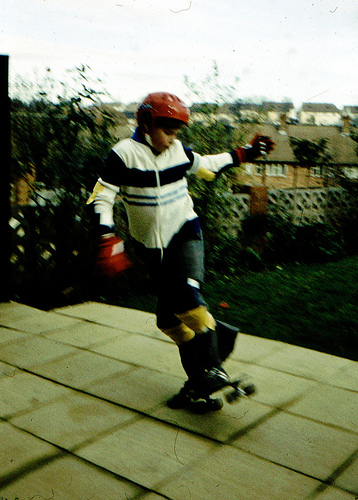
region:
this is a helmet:
[147, 71, 218, 172]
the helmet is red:
[113, 121, 179, 169]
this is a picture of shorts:
[126, 243, 221, 320]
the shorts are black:
[145, 236, 226, 319]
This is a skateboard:
[187, 376, 260, 399]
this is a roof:
[270, 141, 295, 163]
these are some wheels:
[142, 360, 267, 421]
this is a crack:
[156, 339, 177, 488]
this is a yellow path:
[167, 300, 215, 336]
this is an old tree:
[56, 177, 82, 267]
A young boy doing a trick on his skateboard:
[75, 88, 275, 416]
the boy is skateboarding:
[88, 84, 287, 418]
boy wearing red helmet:
[130, 87, 196, 140]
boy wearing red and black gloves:
[70, 96, 286, 412]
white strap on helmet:
[146, 125, 159, 150]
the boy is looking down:
[77, 92, 279, 417]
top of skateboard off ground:
[203, 372, 258, 408]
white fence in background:
[5, 184, 352, 288]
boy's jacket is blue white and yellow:
[89, 132, 234, 253]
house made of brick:
[241, 159, 357, 188]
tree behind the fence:
[8, 77, 131, 201]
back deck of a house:
[3, 301, 355, 498]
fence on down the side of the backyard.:
[9, 189, 353, 268]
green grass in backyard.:
[125, 254, 354, 358]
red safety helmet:
[134, 94, 190, 121]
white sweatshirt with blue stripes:
[88, 133, 240, 250]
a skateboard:
[168, 378, 254, 419]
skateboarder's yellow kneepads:
[159, 309, 212, 342]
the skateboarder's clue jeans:
[155, 243, 239, 372]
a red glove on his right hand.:
[96, 238, 130, 272]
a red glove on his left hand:
[235, 136, 275, 164]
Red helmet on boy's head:
[136, 92, 189, 126]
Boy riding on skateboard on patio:
[85, 91, 277, 414]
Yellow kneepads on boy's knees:
[157, 304, 217, 344]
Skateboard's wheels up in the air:
[167, 374, 257, 413]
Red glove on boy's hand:
[95, 236, 132, 277]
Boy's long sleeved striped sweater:
[85, 126, 240, 262]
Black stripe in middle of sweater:
[123, 163, 187, 189]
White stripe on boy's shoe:
[215, 370, 228, 381]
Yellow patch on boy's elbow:
[195, 166, 214, 180]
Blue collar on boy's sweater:
[130, 126, 146, 143]